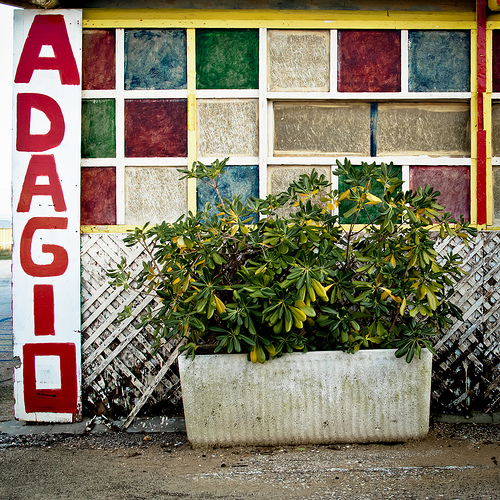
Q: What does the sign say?
A: Adagio.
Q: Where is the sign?
A: On the left.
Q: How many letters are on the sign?
A: Six.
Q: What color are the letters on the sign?
A: Red.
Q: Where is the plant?
A: On the right.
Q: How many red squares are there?
A: Four.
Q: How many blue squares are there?
A: Three.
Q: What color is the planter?
A: White.